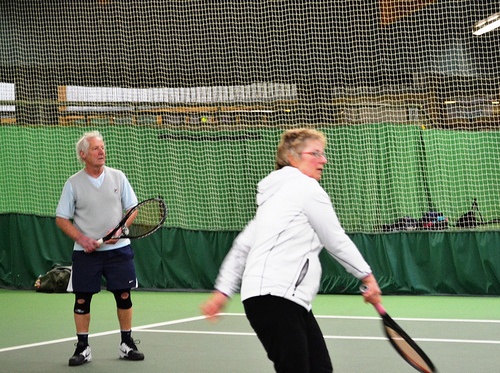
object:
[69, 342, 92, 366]
shoe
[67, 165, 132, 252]
sweater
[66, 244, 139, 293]
shorts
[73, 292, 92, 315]
knee brace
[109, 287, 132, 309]
knee brace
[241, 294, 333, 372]
pants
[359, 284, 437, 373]
racket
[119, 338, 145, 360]
shoe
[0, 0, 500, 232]
green net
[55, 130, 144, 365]
male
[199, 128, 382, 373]
female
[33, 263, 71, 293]
bag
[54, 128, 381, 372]
two people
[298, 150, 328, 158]
eyeglasses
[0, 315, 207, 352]
line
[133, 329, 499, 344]
line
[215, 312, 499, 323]
line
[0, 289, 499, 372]
floor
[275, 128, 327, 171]
hair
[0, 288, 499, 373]
tennis court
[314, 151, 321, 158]
woman's eyes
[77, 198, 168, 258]
racket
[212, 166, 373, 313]
hoodie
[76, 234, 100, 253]
hand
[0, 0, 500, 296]
wall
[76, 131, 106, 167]
hair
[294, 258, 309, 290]
pocket